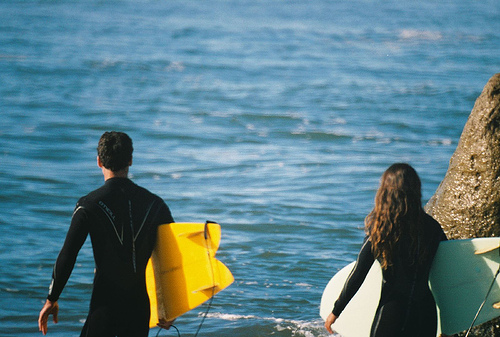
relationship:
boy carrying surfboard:
[44, 122, 187, 336] [142, 218, 242, 333]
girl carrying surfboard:
[326, 159, 451, 336] [313, 231, 483, 333]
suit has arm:
[333, 202, 453, 337] [324, 233, 378, 334]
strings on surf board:
[189, 216, 269, 262] [137, 213, 259, 311]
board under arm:
[323, 232, 500, 337] [431, 215, 451, 244]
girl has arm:
[326, 159, 451, 336] [431, 215, 451, 244]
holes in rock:
[457, 148, 488, 178] [418, 74, 499, 215]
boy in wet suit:
[44, 122, 187, 336] [102, 206, 135, 277]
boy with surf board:
[44, 122, 187, 336] [130, 205, 242, 309]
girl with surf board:
[326, 159, 451, 336] [298, 247, 375, 326]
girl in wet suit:
[326, 159, 451, 336] [396, 240, 422, 316]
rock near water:
[404, 62, 498, 202] [161, 34, 380, 161]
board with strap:
[146, 219, 233, 331] [200, 211, 222, 275]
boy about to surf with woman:
[44, 122, 187, 336] [355, 153, 445, 334]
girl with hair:
[364, 155, 483, 334] [367, 154, 423, 234]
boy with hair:
[44, 110, 186, 333] [78, 126, 144, 175]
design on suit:
[94, 193, 166, 275] [50, 185, 181, 336]